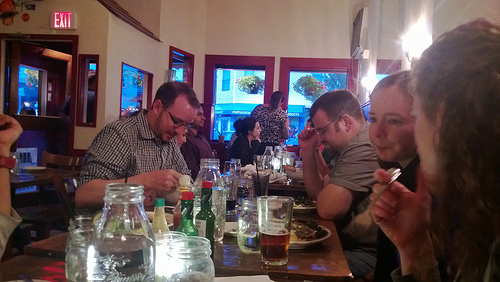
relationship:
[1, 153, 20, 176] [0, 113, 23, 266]
watch on arm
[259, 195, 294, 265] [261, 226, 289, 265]
glass has beer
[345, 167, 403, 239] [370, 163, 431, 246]
fork in woman's hand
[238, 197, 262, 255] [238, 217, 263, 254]
jar filled with water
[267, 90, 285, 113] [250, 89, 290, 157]
pony tail on woman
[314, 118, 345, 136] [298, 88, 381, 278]
glasses being touched by man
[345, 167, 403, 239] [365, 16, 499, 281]
fork held by people eating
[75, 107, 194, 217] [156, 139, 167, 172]
shirt type button down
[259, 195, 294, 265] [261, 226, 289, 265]
glass filled with liquid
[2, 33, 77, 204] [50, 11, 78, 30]
door under exit sign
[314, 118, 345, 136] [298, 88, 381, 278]
glasses on man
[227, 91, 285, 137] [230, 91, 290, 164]
pony tails on women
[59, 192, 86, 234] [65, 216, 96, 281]
straw in drink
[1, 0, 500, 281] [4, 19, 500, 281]
restaurant with people eating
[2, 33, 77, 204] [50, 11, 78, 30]
door near exit sign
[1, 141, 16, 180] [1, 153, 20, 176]
woman's wrist has a red watch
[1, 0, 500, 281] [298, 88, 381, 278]
restaurant with an eating man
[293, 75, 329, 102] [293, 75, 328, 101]
red flowers in a red flowers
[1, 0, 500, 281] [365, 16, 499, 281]
restaurant has a sitting people eating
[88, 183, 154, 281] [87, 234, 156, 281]
bottle filled with water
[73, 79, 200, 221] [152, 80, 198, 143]
person with a head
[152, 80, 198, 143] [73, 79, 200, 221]
head on a person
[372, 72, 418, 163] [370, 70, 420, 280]
head on a person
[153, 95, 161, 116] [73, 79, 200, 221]
ear on person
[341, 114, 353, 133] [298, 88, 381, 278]
ear on person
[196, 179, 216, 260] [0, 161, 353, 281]
bottle atop a table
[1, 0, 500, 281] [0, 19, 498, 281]
restaurant filled with people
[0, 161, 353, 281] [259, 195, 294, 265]
table under a glass of beer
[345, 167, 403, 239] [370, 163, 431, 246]
fork in woman's right hand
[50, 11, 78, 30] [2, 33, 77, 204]
exit sign atop door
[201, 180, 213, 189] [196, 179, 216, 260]
red lid on green bottle